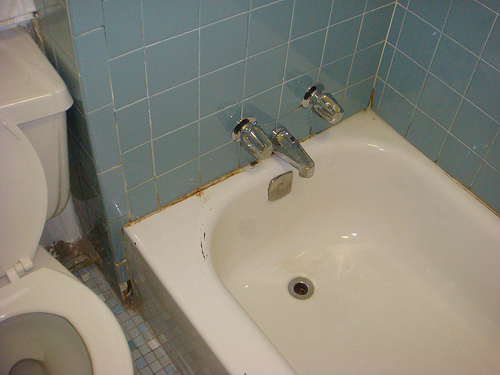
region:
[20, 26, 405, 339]
bathtub and toilet in bathroom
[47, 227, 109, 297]
tile on floor behind toilet in need of repair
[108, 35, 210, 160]
square blue tiles on wall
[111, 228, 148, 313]
bottom section of blue tile is broken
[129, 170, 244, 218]
rust stains between tile and tub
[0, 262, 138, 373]
toilet set is down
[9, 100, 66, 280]
toilet lid is up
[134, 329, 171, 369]
tiny blue mosaic tiles on floor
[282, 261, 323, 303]
drain for bathtub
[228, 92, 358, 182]
silver faucets and spout for tub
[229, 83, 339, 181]
a bathtub foset and two handles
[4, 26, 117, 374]
a toilet bowl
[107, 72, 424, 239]
a very dirty bathub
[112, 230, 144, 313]
a crack in the tiles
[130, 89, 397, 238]
soap buildup all around the bathtub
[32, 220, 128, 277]
a dirty wall corner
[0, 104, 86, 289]
a toilet bowl lid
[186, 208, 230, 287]
a black scratch mark on the bathub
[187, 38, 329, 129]
reflection of the bathub foset and handles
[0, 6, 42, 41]
a towel hanging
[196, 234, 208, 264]
black dirt on the tub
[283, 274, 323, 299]
a metal drain in the tun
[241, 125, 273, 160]
a silver control knob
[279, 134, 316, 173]
a shiny metal tub faucet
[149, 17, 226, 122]
blue tile on the wall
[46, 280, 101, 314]
the white seat on the toliet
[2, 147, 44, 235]
the rounded white toilet lid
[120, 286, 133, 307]
brown stains on the floor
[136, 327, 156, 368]
blue and white tiles on the floor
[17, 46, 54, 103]
the water tank on the toilet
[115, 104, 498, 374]
an empty white bathtub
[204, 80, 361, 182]
silver spigot and water controls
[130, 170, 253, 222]
dirty brown grout in the shower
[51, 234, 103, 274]
brown ugly dirt on the floor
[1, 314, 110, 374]
toilet bowl with water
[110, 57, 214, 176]
light blue tile on the wall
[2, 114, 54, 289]
toilet lid that is up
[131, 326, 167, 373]
small blue and white tiles on the floor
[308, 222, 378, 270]
shiny light reflection on the tub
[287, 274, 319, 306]
drain in the bottom of the tub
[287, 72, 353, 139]
the knob is silver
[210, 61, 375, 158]
there are 2 knobs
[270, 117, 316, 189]
the water spout is silver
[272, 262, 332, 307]
the drain is open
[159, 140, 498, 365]
the tub is clean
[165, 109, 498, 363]
the tub is white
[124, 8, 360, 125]
the wall is made of tile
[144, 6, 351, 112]
the tiles are light blue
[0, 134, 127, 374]
the toilet lid is up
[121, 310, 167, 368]
the tiles on the floor are white and blue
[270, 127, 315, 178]
a chrome bath tub faucet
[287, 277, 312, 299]
a chrome bath tub drain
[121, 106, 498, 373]
a white bath tub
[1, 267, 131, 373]
a white plastic toilet seat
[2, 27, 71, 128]
a white porcelain toilet tank lid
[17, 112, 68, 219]
a white porcelain toilet tank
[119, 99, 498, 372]
white tub in bathroom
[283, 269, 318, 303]
silver drain on bottom of bath tub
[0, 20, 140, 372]
white toilet in bathroom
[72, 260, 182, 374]
blue and white tile on bathroom floor